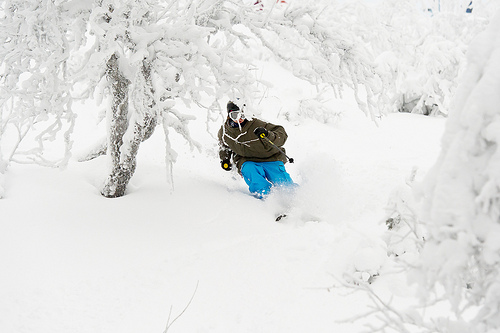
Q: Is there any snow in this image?
A: Yes, there is snow.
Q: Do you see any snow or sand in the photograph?
A: Yes, there is snow.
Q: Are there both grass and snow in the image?
A: No, there is snow but no grass.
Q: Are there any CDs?
A: No, there are no cds.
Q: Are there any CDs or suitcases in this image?
A: No, there are no CDs or suitcases.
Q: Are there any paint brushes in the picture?
A: No, there are no paint brushes.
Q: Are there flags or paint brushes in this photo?
A: No, there are no paint brushes or flags.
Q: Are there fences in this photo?
A: No, there are no fences.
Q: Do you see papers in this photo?
A: No, there are no papers.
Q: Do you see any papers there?
A: No, there are no papers.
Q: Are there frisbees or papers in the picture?
A: No, there are no papers or frisbees.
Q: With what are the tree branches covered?
A: The branches are covered with snow.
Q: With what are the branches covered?
A: The branches are covered with snow.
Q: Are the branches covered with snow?
A: Yes, the branches are covered with snow.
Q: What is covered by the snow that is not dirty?
A: The branches are covered by the snow.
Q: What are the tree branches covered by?
A: The branches are covered by the snow.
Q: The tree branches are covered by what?
A: The branches are covered by the snow.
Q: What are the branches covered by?
A: The branches are covered by the snow.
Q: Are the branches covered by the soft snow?
A: Yes, the branches are covered by the snow.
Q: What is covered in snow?
A: The branches are covered in snow.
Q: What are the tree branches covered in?
A: The branches are covered in snow.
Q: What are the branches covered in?
A: The branches are covered in snow.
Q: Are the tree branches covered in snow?
A: Yes, the branches are covered in snow.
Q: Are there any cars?
A: No, there are no cars.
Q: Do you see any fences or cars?
A: No, there are no cars or fences.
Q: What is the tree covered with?
A: The tree is covered with snow.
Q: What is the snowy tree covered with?
A: The tree is covered with snow.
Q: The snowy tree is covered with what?
A: The tree is covered with snow.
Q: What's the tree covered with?
A: The tree is covered with snow.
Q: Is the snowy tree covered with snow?
A: Yes, the tree is covered with snow.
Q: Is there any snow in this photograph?
A: Yes, there is snow.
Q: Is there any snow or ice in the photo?
A: Yes, there is snow.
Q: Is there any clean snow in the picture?
A: Yes, there is clean snow.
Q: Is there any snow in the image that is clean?
A: Yes, there is snow that is clean.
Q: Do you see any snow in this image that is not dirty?
A: Yes, there is clean snow.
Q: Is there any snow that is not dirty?
A: Yes, there is clean snow.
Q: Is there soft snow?
A: Yes, there is soft snow.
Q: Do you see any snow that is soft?
A: Yes, there is snow that is soft.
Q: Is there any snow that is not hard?
A: Yes, there is soft snow.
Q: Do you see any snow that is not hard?
A: Yes, there is soft snow.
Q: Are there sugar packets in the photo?
A: No, there are no sugar packets.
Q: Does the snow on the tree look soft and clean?
A: Yes, the snow is soft and clean.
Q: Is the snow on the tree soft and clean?
A: Yes, the snow is soft and clean.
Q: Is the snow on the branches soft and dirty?
A: No, the snow is soft but clean.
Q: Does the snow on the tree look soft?
A: Yes, the snow is soft.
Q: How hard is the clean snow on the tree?
A: The snow is soft.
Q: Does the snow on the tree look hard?
A: No, the snow is soft.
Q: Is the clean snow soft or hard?
A: The snow is soft.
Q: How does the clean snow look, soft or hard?
A: The snow is soft.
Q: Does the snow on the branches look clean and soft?
A: Yes, the snow is clean and soft.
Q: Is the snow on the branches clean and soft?
A: Yes, the snow is clean and soft.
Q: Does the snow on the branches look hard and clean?
A: No, the snow is clean but soft.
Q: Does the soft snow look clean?
A: Yes, the snow is clean.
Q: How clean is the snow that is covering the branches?
A: The snow is clean.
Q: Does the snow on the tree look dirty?
A: No, the snow is clean.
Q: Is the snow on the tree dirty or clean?
A: The snow is clean.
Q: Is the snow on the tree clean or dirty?
A: The snow is clean.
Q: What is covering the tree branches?
A: The snow is covering the branches.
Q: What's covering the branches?
A: The snow is covering the branches.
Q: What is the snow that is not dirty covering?
A: The snow is covering the branches.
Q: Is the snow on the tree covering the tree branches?
A: Yes, the snow is covering the branches.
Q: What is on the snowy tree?
A: The snow is on the tree.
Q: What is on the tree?
A: The snow is on the tree.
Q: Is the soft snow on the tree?
A: Yes, the snow is on the tree.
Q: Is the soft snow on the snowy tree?
A: Yes, the snow is on the tree.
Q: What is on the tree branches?
A: The snow is on the branches.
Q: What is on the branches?
A: The snow is on the branches.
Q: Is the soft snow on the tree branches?
A: Yes, the snow is on the branches.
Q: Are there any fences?
A: No, there are no fences.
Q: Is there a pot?
A: No, there are no pots.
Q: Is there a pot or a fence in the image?
A: No, there are no pots or fences.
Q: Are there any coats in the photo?
A: Yes, there is a coat.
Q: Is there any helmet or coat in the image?
A: Yes, there is a coat.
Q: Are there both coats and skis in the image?
A: Yes, there are both a coat and skis.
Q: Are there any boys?
A: No, there are no boys.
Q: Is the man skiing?
A: Yes, the man is skiing.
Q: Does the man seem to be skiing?
A: Yes, the man is skiing.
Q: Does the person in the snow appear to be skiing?
A: Yes, the man is skiing.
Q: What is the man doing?
A: The man is skiing.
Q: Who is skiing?
A: The man is skiing.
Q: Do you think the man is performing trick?
A: No, the man is skiing.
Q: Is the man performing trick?
A: No, the man is skiing.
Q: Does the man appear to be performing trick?
A: No, the man is skiing.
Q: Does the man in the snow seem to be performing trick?
A: No, the man is skiing.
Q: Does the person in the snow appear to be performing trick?
A: No, the man is skiing.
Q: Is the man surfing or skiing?
A: The man is skiing.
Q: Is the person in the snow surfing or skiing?
A: The man is skiing.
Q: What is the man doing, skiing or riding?
A: The man is skiing.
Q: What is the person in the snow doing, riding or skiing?
A: The man is skiing.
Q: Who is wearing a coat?
A: The man is wearing a coat.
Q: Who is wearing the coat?
A: The man is wearing a coat.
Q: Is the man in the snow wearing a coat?
A: Yes, the man is wearing a coat.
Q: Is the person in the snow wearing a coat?
A: Yes, the man is wearing a coat.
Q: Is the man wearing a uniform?
A: No, the man is wearing a coat.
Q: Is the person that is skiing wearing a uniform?
A: No, the man is wearing a coat.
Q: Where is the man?
A: The man is in the snow.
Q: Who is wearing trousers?
A: The man is wearing trousers.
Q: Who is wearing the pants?
A: The man is wearing trousers.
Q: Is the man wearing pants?
A: Yes, the man is wearing pants.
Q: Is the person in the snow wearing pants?
A: Yes, the man is wearing pants.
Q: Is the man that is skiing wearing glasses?
A: No, the man is wearing pants.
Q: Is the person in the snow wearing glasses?
A: No, the man is wearing pants.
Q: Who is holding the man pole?
A: The man is holding the pole.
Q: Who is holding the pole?
A: The man is holding the pole.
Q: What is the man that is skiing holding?
A: The man is holding the pole.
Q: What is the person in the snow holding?
A: The man is holding the pole.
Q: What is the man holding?
A: The man is holding the pole.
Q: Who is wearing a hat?
A: The man is wearing a hat.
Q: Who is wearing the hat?
A: The man is wearing a hat.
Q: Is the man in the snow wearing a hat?
A: Yes, the man is wearing a hat.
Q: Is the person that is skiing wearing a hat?
A: Yes, the man is wearing a hat.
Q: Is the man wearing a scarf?
A: No, the man is wearing a hat.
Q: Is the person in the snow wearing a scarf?
A: No, the man is wearing a hat.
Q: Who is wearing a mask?
A: The man is wearing a mask.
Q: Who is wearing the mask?
A: The man is wearing a mask.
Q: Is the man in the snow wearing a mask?
A: Yes, the man is wearing a mask.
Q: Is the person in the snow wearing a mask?
A: Yes, the man is wearing a mask.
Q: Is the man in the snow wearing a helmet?
A: No, the man is wearing a mask.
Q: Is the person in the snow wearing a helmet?
A: No, the man is wearing a mask.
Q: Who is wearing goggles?
A: The man is wearing goggles.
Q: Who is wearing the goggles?
A: The man is wearing goggles.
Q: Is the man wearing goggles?
A: Yes, the man is wearing goggles.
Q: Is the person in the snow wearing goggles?
A: Yes, the man is wearing goggles.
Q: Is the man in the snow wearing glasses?
A: No, the man is wearing goggles.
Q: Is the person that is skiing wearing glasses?
A: No, the man is wearing goggles.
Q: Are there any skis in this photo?
A: Yes, there are skis.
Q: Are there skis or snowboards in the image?
A: Yes, there are skis.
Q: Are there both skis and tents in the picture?
A: No, there are skis but no tents.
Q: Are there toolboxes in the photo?
A: No, there are no toolboxes.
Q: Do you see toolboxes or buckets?
A: No, there are no toolboxes or buckets.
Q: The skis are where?
A: The skis are in the snow.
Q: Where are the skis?
A: The skis are in the snow.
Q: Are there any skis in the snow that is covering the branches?
A: Yes, there are skis in the snow.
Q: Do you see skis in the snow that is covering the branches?
A: Yes, there are skis in the snow.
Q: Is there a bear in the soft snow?
A: No, there are skis in the snow.